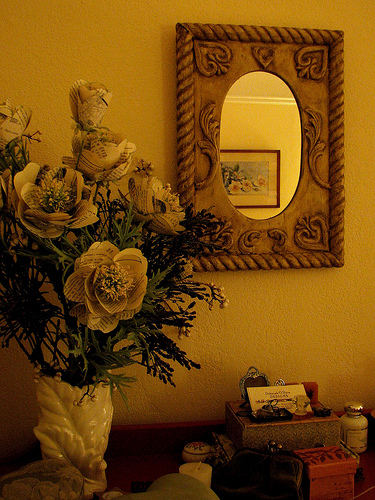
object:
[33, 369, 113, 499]
vase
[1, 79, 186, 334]
roses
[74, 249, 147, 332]
newspaper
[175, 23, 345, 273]
mirror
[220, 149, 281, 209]
reflection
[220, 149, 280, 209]
art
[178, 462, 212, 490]
candle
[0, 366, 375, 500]
knick knacks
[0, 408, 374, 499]
table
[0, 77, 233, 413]
leaves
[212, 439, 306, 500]
coin purse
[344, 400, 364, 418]
cap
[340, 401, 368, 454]
jar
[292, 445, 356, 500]
box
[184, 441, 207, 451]
flowers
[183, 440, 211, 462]
porcelain box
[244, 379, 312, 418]
business card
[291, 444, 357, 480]
lid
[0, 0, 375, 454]
wall